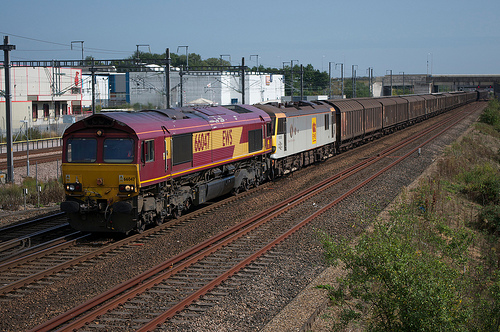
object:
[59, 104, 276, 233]
engine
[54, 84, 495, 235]
train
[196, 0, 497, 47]
sky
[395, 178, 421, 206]
foliage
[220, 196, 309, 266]
tracks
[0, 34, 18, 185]
pole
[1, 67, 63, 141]
building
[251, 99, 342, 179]
secondary engine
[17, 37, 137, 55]
wires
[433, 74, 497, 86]
bridge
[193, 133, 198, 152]
numbers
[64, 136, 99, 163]
windows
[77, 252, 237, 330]
railroad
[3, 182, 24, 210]
bushes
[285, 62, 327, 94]
trees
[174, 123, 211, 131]
stripe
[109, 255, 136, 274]
gravel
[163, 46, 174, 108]
poles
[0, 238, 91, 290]
tracks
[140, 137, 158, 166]
side windows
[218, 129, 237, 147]
writing